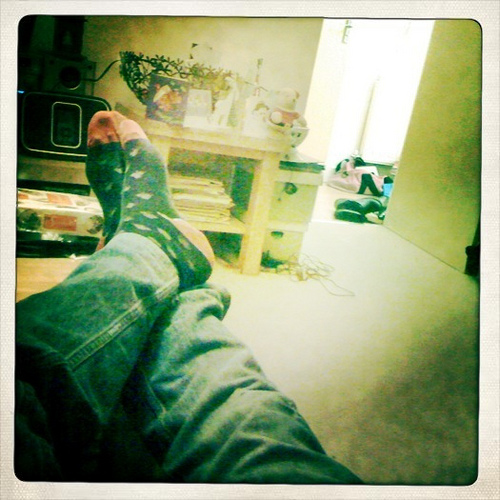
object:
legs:
[95, 109, 367, 482]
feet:
[108, 109, 217, 286]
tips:
[112, 106, 149, 148]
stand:
[127, 103, 284, 274]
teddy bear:
[268, 81, 308, 130]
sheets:
[167, 165, 235, 225]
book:
[140, 73, 189, 130]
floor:
[20, 271, 479, 485]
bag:
[327, 151, 384, 200]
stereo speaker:
[20, 85, 112, 163]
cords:
[260, 253, 353, 301]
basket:
[118, 45, 241, 124]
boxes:
[254, 162, 324, 267]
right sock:
[82, 110, 122, 256]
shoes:
[334, 206, 387, 225]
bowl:
[261, 115, 309, 153]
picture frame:
[182, 84, 216, 133]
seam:
[27, 278, 180, 410]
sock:
[117, 109, 214, 289]